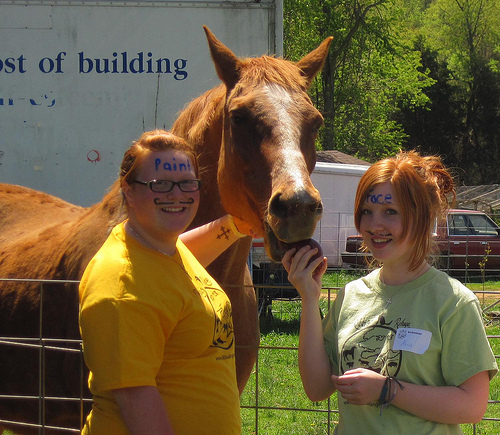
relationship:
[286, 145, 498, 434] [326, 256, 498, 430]
girl wearing shirt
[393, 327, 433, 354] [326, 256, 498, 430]
nametag on her shirt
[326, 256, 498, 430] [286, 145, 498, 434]
shirt of girl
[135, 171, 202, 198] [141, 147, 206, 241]
glasses on her face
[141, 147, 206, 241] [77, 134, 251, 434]
face of girl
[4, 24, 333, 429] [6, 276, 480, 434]
horse behind fence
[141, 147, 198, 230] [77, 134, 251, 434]
face of girl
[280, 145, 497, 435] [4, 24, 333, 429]
girl with horse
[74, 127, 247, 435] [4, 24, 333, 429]
girl with horse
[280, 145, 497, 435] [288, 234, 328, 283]
girl eating an apple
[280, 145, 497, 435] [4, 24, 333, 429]
girl feeding horse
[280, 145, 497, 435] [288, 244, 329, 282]
girl holding an apple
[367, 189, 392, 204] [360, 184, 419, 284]
blue in girls face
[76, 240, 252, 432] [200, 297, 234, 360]
shirt has print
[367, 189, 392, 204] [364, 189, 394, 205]
blue i think also painted in blue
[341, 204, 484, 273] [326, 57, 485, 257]
car in the background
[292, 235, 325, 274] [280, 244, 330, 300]
apple in the hand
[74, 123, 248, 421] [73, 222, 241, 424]
girl wearing a shirt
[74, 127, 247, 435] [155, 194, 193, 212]
girl has mustache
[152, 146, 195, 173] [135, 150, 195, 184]
paint on forehead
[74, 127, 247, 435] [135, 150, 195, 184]
girl has forehead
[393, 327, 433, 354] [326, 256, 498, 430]
nametag on shirt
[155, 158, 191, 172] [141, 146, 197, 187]
paint on forehead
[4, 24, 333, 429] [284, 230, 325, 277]
horse eats apple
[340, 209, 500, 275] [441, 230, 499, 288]
car next fence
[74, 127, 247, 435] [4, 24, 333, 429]
girl by horse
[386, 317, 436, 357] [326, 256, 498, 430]
nametag on shirt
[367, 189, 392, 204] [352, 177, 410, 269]
blue on face